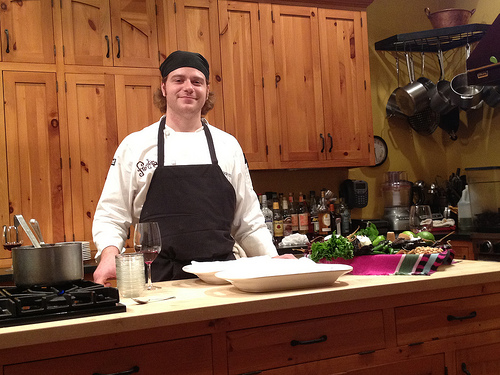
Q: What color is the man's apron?
A: Black.